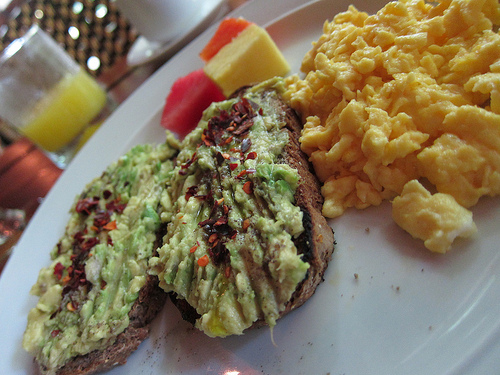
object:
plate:
[0, 0, 500, 375]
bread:
[170, 84, 337, 328]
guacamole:
[20, 140, 178, 370]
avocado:
[146, 96, 311, 340]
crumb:
[354, 273, 358, 279]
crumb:
[365, 227, 369, 231]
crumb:
[397, 286, 400, 291]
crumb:
[428, 326, 432, 331]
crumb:
[307, 342, 312, 346]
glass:
[0, 23, 108, 151]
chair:
[0, 0, 142, 79]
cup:
[109, 0, 221, 46]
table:
[105, 67, 139, 87]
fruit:
[159, 17, 289, 135]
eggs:
[281, 0, 500, 253]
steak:
[32, 142, 170, 375]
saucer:
[125, 0, 230, 68]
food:
[20, 0, 500, 375]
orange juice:
[17, 67, 106, 152]